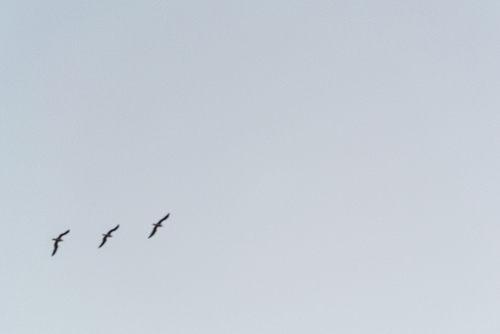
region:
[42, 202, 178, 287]
three birds flying in group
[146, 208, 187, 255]
black bird flying in sky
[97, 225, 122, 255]
black bird flying in sky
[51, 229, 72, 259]
black bird flying in sky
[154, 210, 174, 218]
wing of black bird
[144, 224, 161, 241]
wing of black bird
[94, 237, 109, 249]
wing of black bird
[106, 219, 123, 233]
wing of black bird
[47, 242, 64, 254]
wing of black bird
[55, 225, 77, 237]
wing of black bird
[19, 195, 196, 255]
Three birds in formation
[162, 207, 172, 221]
Left wing of bird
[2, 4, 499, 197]
Sky is slate gray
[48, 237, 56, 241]
Tail of bird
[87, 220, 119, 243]
Bird in middle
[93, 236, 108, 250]
Right wing of middle bird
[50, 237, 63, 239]
Body of bird in back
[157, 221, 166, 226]
Head of bird in front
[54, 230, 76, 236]
Left wing of backmost bird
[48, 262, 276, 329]
Space underneath birds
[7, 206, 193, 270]
Birds in the sky.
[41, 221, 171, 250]
The bodies are brown.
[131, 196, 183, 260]
The wings are black.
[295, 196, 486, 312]
The sky is blue.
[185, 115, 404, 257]
The sky is clear.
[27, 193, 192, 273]
The birds are flying.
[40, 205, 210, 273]
Birds in a line.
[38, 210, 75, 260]
The wings are curved.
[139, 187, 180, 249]
The wings are straight.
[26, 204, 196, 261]
There are three birds.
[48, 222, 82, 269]
black bird flying in sky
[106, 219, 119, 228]
wing of black bird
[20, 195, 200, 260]
group of three birds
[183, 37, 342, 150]
The sky is blue.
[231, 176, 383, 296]
The sky is clear.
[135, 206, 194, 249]
The wings are spread.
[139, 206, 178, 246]
The wings are black.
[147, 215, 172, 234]
The body is brown.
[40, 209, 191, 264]
The birds are in a line.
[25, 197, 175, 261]
Birds are flying.